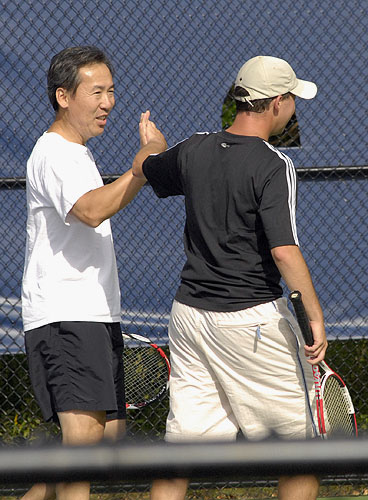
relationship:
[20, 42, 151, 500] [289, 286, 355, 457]
man carrying racket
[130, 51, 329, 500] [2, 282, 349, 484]
man on court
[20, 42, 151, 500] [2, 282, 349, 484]
man on court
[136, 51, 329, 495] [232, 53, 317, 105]
man wearing cap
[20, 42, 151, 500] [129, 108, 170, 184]
man are touching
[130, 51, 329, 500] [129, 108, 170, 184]
man are touching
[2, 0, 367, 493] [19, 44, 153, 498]
fence behind man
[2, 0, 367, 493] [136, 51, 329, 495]
fence behind man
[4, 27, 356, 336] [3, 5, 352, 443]
screen behind fence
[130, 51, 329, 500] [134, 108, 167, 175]
man touching palms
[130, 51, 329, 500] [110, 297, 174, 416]
man holding racket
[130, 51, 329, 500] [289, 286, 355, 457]
man holding racket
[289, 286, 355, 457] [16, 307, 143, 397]
racket below waist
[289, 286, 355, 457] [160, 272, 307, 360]
racket below waist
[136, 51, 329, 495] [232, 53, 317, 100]
man wearing cap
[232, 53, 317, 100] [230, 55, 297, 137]
cap on head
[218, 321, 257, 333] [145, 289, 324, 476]
pocket on shorts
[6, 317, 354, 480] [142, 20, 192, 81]
plants growing near fence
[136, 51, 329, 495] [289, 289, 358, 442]
man holding racket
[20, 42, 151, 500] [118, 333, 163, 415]
man holding racket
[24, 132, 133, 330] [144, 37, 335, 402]
shirt on player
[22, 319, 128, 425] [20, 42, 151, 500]
shorts on man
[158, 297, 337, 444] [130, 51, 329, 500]
shorts on man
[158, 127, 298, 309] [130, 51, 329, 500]
black shirt on man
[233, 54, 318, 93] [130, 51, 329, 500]
hat on man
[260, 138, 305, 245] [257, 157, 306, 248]
stripes on sleeve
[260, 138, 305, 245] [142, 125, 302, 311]
stripes on shirt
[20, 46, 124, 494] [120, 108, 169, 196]
man holding hands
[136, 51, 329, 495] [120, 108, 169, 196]
man holding hands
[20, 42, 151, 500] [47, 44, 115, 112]
man has hair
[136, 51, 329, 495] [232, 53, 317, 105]
man wearing a cap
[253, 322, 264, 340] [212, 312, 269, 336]
zipper on pocket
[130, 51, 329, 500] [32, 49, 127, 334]
man high highfiving man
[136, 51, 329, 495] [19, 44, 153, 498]
man touching hands with man